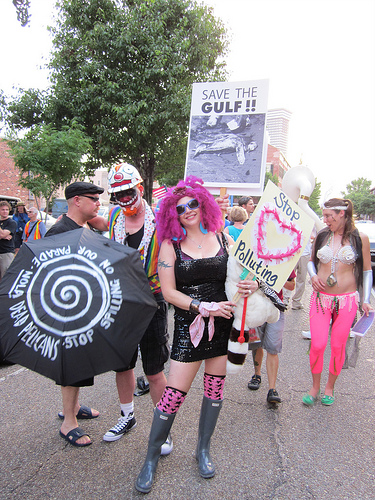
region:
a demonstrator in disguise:
[133, 177, 298, 492]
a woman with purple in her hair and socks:
[128, 175, 261, 494]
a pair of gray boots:
[131, 393, 231, 495]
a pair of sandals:
[53, 401, 103, 455]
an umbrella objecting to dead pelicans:
[0, 224, 158, 382]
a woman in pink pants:
[297, 196, 373, 406]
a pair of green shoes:
[299, 387, 340, 409]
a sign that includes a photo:
[189, 78, 275, 192]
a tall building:
[263, 105, 291, 155]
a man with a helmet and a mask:
[103, 157, 145, 220]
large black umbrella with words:
[0, 231, 151, 383]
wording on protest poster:
[193, 88, 269, 116]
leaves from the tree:
[71, 77, 182, 127]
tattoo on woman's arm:
[153, 257, 179, 273]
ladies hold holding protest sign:
[234, 184, 314, 296]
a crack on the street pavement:
[20, 456, 98, 495]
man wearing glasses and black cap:
[57, 181, 104, 223]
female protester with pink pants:
[302, 197, 372, 423]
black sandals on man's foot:
[57, 427, 93, 447]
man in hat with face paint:
[102, 168, 150, 214]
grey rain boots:
[134, 390, 240, 497]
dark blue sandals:
[48, 395, 113, 451]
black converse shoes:
[103, 392, 187, 463]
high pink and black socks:
[131, 366, 264, 496]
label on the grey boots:
[155, 411, 176, 425]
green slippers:
[300, 399, 347, 407]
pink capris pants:
[302, 277, 359, 384]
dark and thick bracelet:
[175, 292, 205, 310]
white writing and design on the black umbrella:
[3, 242, 131, 354]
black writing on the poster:
[248, 191, 309, 293]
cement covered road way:
[244, 426, 345, 495]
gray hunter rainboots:
[116, 406, 256, 471]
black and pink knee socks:
[167, 375, 241, 426]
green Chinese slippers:
[288, 388, 360, 417]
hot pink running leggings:
[310, 304, 368, 395]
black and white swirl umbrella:
[28, 227, 159, 389]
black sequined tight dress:
[152, 242, 243, 448]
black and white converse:
[94, 409, 175, 467]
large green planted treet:
[49, 16, 234, 151]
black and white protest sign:
[189, 54, 294, 248]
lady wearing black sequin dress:
[124, 165, 266, 496]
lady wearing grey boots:
[134, 362, 254, 498]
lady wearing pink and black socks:
[145, 366, 244, 432]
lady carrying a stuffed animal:
[211, 191, 301, 411]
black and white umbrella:
[6, 213, 152, 411]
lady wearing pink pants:
[279, 185, 370, 415]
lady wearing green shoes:
[296, 378, 346, 429]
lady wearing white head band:
[316, 190, 374, 237]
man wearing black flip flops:
[43, 390, 142, 471]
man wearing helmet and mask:
[93, 147, 156, 257]